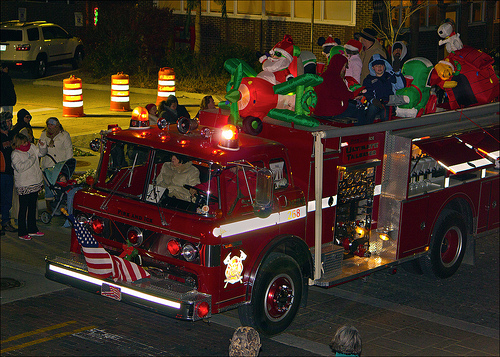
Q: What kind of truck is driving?
A: Fire.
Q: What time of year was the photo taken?
A: Christmas.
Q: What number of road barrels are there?
A: 3.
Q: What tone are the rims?
A: Red.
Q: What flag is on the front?
A: USA.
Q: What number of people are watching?
A: 5.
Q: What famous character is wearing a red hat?
A: Santa.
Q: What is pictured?
A: Firetruck.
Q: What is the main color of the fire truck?
A: Red.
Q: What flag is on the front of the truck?
A: American.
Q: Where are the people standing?
A: On the corner.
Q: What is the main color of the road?
A: Gray.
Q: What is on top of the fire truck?
A: Balloons.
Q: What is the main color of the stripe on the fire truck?
A: White.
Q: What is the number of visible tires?
A: 2.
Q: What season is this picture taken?
A: Christmas.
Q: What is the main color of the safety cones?
A: Orange.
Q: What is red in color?
A: Fire truck.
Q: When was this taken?
A: Christmas time.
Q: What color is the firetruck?
A: Red.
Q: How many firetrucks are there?
A: 1.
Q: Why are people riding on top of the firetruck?
A: Parade.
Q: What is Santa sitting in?
A: Airplane.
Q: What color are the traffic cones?
A: Orange.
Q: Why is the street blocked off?
A: Parade.